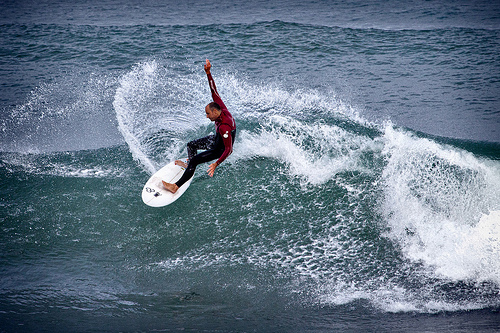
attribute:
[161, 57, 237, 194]
man — balancing, balding, middle aged, adept, practiced, shoeless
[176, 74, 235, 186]
wet suit — colorful, slick, clingy, red, black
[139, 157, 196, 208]
surfboard — white, swaying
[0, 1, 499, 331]
ocean — blue, choppy, clear, calm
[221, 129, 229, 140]
logo — white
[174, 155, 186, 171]
foot — bare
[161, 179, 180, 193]
foot — bare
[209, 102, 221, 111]
hair — graying, black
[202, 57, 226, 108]
arm — extended